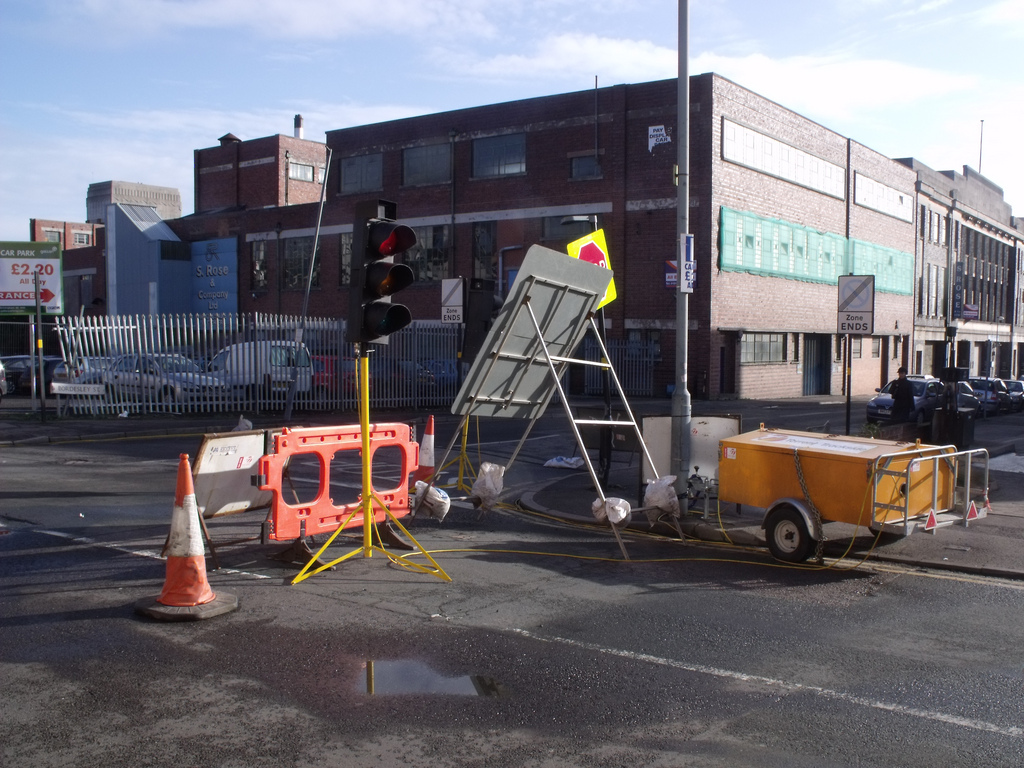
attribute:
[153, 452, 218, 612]
traffic cone — white striped, orange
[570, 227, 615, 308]
sign — red, yellow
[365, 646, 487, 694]
puddle — mud, small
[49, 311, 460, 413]
fence — tall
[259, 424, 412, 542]
barrier section — plastic, orange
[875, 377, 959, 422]
car — parked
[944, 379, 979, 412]
car — parked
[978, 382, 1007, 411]
car — parked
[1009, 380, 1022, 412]
car — parked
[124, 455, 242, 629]
cone — white, orange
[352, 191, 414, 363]
traffic signal — black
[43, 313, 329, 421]
fence — tall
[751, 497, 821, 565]
wheel — small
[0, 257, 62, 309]
sign — red, white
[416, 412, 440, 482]
cone — white, orange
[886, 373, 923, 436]
dress — black